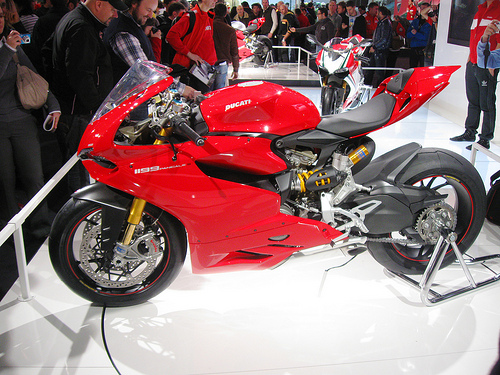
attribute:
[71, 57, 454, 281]
motorbike — sleek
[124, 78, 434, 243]
motorcycle — red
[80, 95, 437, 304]
bike — reddish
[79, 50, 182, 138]
window — curved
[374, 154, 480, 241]
tire — rubber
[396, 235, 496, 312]
stand — metal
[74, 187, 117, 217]
fender — black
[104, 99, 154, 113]
sleeve — plaid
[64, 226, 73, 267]
outline — red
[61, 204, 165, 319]
rubber — black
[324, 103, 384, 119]
seat — black,  leather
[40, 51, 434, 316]
motorcycle — fancy, red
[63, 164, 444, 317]
wheels — black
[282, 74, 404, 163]
seat — black,  leather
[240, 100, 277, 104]
jacket — red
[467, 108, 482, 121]
jacket — red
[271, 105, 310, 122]
jacket — brown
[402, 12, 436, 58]
shirt — blue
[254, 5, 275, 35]
vest — brown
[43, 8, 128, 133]
shirt — black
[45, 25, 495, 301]
motorbike — red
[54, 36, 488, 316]
motorbike — red, white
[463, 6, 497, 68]
shirt — red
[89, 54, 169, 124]
windshield — small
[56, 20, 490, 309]
motorcycle — red, displayed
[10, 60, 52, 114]
purse — one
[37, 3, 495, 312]
motorcycle — red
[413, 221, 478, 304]
stand — silver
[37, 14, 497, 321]
bike — black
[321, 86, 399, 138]
seat — black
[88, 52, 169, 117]
windshield — clear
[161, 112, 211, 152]
handle bar — black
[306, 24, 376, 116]
bike — white, red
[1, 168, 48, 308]
railing — white, metal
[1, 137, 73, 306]
railing — metal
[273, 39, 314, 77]
railing — white, metal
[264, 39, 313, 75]
railing — metal, white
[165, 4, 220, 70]
sweater — red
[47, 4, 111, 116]
sweater — black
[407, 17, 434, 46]
jacket — blue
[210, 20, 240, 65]
jacket — brown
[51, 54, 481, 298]
motorcycle — red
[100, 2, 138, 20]
baseball cap — black